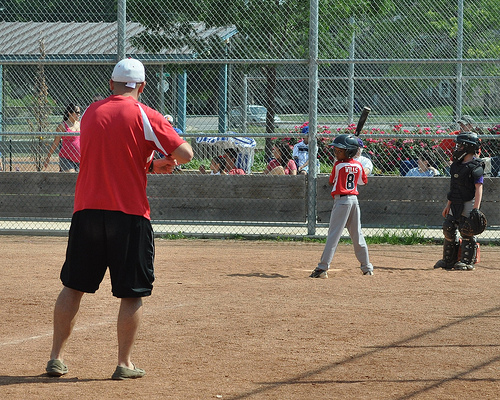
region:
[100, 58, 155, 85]
white hat on coach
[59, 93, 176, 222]
red and white shirt on coach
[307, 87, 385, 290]
player at bat on field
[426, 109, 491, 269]
player watch to catch the ball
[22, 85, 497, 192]
group of people watching the game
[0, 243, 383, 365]
baseball diamond drawn on the field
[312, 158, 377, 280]
baseball uniform worn by player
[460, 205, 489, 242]
black baseball mitt on player's hand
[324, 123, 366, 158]
black helmet on player's head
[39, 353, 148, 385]
brown shoes on coach's feet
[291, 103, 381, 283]
kid holding baseball bat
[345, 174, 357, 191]
number on back of jersey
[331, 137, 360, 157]
helmet on the player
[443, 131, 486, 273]
catcher standing behind batter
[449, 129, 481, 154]
catcher's mask on kid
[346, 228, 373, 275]
leg of the batter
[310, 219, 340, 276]
leg of the batter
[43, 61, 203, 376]
coach standing on field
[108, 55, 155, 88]
hat on the coach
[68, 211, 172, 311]
black shorts on man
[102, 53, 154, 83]
White hat on man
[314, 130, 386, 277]
Child waiting to bat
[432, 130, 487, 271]
Catcher in protective gear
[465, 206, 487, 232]
Catcher's mitt on boy's hand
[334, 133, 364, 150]
Black helmet on boy's head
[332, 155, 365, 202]
Red baseball jersey on boy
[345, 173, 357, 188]
Black number on red shirt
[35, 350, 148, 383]
Tan loafers on baseball coach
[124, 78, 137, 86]
White tag sticking out from hat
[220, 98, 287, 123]
Silver car behind fence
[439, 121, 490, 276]
catcher in black uniform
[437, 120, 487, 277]
catcher standing up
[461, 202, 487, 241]
black catchers glove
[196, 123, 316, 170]
fans at baseball game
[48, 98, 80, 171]
woman in red shirt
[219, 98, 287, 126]
car in parking lot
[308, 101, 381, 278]
baseball player holding bat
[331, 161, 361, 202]
uniform has number eight on the back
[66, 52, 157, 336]
man dressed in red and black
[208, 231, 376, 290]
shadow of baseball player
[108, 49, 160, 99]
Person wearing white hat.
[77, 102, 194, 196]
Person wearing red and white shirt.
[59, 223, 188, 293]
Person wearing black shorts.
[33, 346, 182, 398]
Person wearing gray shoes.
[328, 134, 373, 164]
Person wearing black helmet.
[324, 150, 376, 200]
Child wearing red and white jersey.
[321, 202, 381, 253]
Child wearing gray pants.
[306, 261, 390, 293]
Child wearing black and white shoes.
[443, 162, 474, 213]
Catcher wearing black padding.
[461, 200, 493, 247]
Catcher has mitt on left hand.